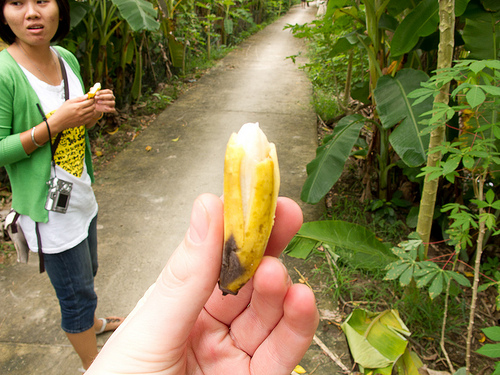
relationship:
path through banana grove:
[0, 2, 321, 373] [2, 1, 497, 373]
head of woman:
[4, 1, 69, 58] [0, 0, 128, 374]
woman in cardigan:
[1, 3, 131, 373] [1, 40, 93, 219]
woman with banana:
[1, 3, 131, 373] [61, 74, 107, 116]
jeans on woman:
[39, 212, 97, 332] [1, 3, 131, 373]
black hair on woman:
[3, 2, 75, 54] [1, 3, 131, 373]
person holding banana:
[81, 192, 318, 374] [217, 120, 279, 294]